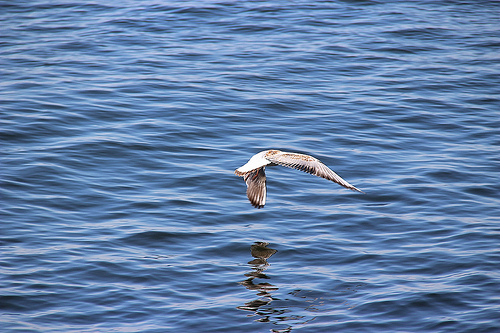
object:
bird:
[232, 149, 366, 210]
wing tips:
[290, 163, 302, 169]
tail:
[232, 160, 265, 179]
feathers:
[231, 161, 264, 178]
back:
[251, 150, 272, 166]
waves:
[228, 21, 285, 34]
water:
[1, 1, 499, 332]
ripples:
[368, 18, 428, 86]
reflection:
[236, 237, 302, 332]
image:
[0, 0, 500, 332]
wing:
[264, 148, 366, 195]